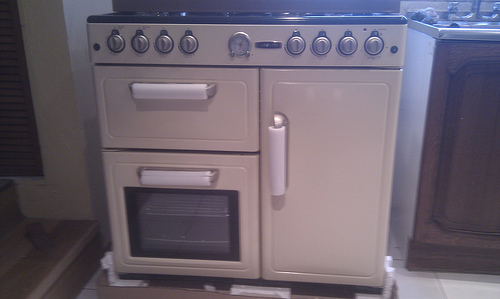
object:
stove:
[86, 12, 408, 25]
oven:
[102, 151, 260, 279]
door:
[113, 163, 248, 270]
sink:
[433, 21, 499, 30]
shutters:
[0, 0, 46, 176]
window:
[0, 0, 47, 178]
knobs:
[180, 30, 198, 53]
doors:
[99, 65, 260, 153]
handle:
[128, 82, 218, 98]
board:
[405, 40, 498, 274]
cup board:
[103, 150, 259, 280]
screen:
[134, 194, 229, 253]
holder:
[266, 112, 288, 196]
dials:
[363, 31, 385, 56]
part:
[429, 28, 446, 43]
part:
[289, 109, 314, 130]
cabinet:
[269, 81, 388, 276]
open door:
[430, 56, 500, 237]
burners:
[295, 9, 388, 19]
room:
[0, 0, 499, 295]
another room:
[2, 180, 42, 232]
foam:
[226, 280, 290, 298]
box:
[92, 270, 357, 299]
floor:
[396, 272, 500, 298]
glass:
[207, 230, 224, 241]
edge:
[382, 15, 392, 26]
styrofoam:
[49, 238, 296, 294]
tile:
[436, 271, 500, 299]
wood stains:
[436, 87, 473, 154]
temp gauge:
[226, 31, 253, 57]